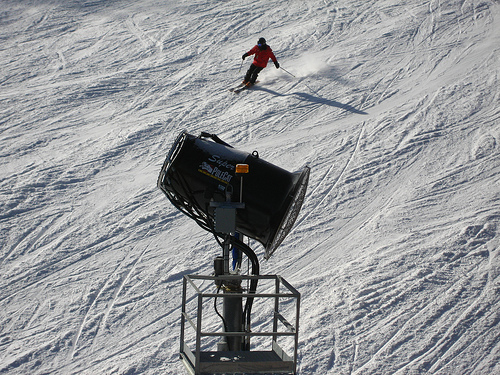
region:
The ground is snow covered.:
[5, 4, 498, 344]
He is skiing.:
[215, 20, 295, 110]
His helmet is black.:
[252, 34, 268, 51]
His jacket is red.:
[241, 44, 279, 71]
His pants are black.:
[234, 62, 265, 87]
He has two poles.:
[225, 37, 304, 101]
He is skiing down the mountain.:
[38, 28, 441, 263]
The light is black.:
[145, 124, 338, 371]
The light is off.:
[142, 119, 320, 362]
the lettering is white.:
[187, 146, 240, 186]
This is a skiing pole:
[274, 60, 329, 107]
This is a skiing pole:
[232, 50, 243, 77]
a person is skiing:
[220, 25, 315, 105]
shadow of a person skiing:
[257, 77, 382, 122]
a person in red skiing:
[223, 24, 398, 140]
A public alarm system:
[121, 128, 356, 370]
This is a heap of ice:
[346, 154, 460, 347]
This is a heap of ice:
[300, 248, 499, 368]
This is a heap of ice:
[82, 204, 176, 366]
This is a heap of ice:
[2, 157, 132, 368]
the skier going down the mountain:
[220, 26, 297, 107]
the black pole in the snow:
[280, 64, 300, 83]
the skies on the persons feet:
[219, 77, 266, 100]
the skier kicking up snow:
[285, 44, 336, 92]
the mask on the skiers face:
[253, 34, 270, 49]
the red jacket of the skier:
[247, 41, 275, 72]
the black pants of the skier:
[242, 61, 266, 85]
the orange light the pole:
[229, 159, 253, 204]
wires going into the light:
[156, 163, 211, 234]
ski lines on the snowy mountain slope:
[340, 160, 494, 372]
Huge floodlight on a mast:
[152, 127, 317, 373]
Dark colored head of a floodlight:
[152, 124, 317, 267]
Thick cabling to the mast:
[194, 227, 260, 330]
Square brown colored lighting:
[233, 161, 250, 177]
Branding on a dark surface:
[198, 150, 238, 185]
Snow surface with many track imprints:
[2, 3, 497, 373]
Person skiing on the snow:
[224, 33, 298, 94]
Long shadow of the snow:
[253, 87, 373, 123]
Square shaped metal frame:
[171, 269, 310, 374]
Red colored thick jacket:
[243, 43, 276, 69]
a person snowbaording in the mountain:
[77, 33, 411, 120]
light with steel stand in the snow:
[152, 124, 327, 374]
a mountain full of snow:
[343, 22, 455, 355]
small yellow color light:
[233, 159, 252, 174]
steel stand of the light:
[170, 268, 311, 364]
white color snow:
[338, 51, 437, 261]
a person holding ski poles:
[230, 34, 291, 96]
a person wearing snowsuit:
[239, 33, 279, 89]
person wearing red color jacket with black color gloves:
[247, 43, 283, 68]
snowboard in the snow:
[230, 83, 252, 96]